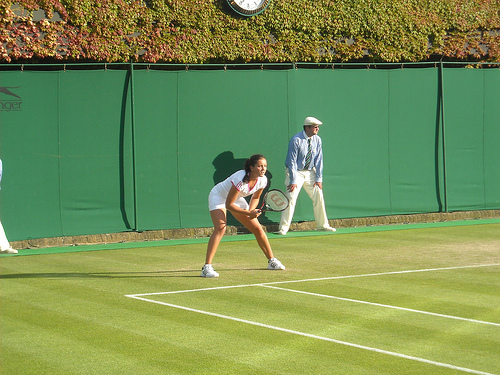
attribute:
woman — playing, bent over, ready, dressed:
[198, 150, 296, 276]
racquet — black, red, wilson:
[257, 189, 294, 214]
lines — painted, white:
[127, 269, 498, 372]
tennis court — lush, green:
[2, 227, 499, 374]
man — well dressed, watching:
[278, 114, 334, 233]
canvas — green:
[4, 69, 498, 234]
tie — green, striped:
[303, 138, 317, 171]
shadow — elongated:
[2, 267, 202, 281]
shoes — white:
[194, 258, 287, 277]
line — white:
[130, 261, 499, 306]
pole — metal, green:
[438, 63, 450, 215]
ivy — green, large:
[2, 4, 496, 56]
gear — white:
[203, 172, 290, 225]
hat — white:
[301, 114, 321, 126]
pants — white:
[277, 170, 333, 228]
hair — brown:
[242, 153, 265, 170]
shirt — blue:
[286, 127, 327, 184]